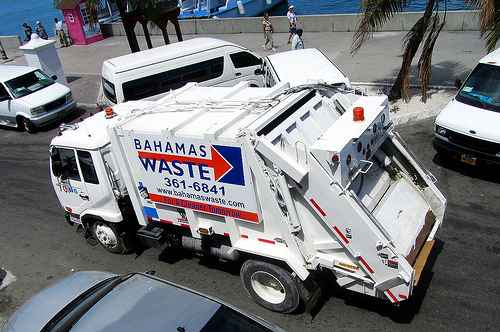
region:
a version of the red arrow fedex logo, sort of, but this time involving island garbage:
[132, 141, 251, 191]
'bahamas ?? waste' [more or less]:
[129, 132, 231, 182]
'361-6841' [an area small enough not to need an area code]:
[160, 174, 230, 199]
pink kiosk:
[55, 0, 107, 50]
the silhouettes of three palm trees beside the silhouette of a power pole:
[109, 0, 201, 64]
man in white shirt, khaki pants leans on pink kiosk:
[49, 16, 73, 51]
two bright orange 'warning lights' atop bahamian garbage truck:
[98, 103, 365, 127]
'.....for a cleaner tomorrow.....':
[148, 189, 256, 224]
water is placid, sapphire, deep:
[0, 1, 499, 42]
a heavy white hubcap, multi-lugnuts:
[88, 218, 123, 254]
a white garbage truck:
[106, 66, 339, 297]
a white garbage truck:
[206, 137, 360, 328]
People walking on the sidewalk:
[243, 1, 340, 63]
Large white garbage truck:
[42, 50, 471, 302]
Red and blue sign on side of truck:
[126, 129, 260, 254]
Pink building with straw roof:
[51, 5, 124, 48]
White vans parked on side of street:
[75, 35, 346, 127]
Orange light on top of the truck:
[346, 101, 390, 137]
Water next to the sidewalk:
[11, 4, 479, 36]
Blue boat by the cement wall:
[153, 3, 281, 35]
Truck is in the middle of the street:
[28, 49, 447, 325]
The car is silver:
[3, 265, 269, 327]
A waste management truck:
[26, 70, 453, 321]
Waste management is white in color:
[45, 56, 455, 316]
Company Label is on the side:
[122, 131, 257, 216]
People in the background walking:
[255, 1, 315, 51]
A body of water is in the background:
[0, 0, 497, 15]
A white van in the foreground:
[420, 46, 495, 176]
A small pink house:
[55, 0, 102, 45]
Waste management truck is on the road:
[30, 85, 455, 326]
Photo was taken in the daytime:
[7, 1, 492, 321]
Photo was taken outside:
[5, 1, 495, 326]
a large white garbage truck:
[80, 65, 377, 272]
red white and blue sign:
[148, 143, 247, 213]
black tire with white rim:
[227, 263, 297, 330]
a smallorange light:
[325, 101, 379, 138]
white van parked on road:
[3, 64, 96, 122]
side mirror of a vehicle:
[18, 138, 63, 206]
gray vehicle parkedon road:
[19, 245, 246, 329]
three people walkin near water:
[217, 1, 312, 72]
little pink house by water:
[7, 0, 114, 73]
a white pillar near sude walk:
[16, 21, 65, 78]